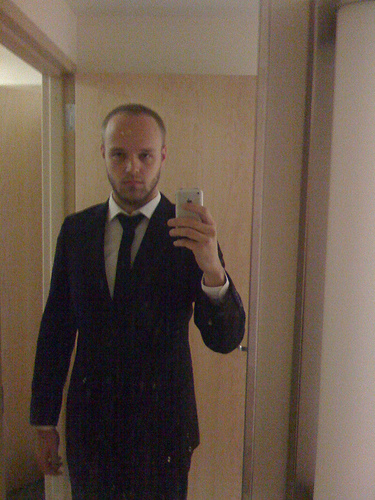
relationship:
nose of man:
[123, 153, 143, 180] [23, 94, 252, 499]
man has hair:
[23, 94, 252, 499] [95, 102, 167, 153]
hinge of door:
[62, 100, 79, 130] [62, 60, 264, 498]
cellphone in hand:
[169, 188, 208, 243] [163, 204, 224, 277]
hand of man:
[163, 204, 224, 277] [23, 94, 252, 499]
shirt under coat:
[100, 192, 165, 304] [27, 188, 249, 466]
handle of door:
[233, 340, 248, 359] [62, 60, 264, 498]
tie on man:
[110, 210, 147, 300] [23, 94, 252, 499]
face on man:
[103, 115, 167, 205] [23, 94, 252, 499]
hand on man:
[29, 428, 67, 479] [23, 94, 252, 499]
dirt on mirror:
[118, 127, 135, 143] [1, 2, 374, 499]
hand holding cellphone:
[163, 204, 224, 277] [169, 188, 208, 243]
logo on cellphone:
[184, 198, 194, 209] [169, 188, 208, 243]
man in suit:
[23, 94, 252, 499] [23, 190, 247, 499]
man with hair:
[23, 94, 252, 499] [95, 102, 167, 153]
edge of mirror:
[357, 0, 375, 33] [1, 2, 374, 499]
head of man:
[97, 101, 171, 217] [23, 94, 252, 499]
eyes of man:
[139, 147, 154, 166] [23, 94, 252, 499]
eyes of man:
[107, 149, 125, 165] [23, 94, 252, 499]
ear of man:
[160, 144, 169, 171] [23, 94, 252, 499]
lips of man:
[122, 177, 145, 190] [23, 94, 252, 499]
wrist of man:
[201, 261, 226, 283] [23, 94, 252, 499]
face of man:
[103, 115, 167, 205] [23, 94, 252, 499]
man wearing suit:
[23, 94, 252, 499] [23, 190, 247, 499]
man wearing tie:
[23, 94, 252, 499] [110, 210, 147, 300]